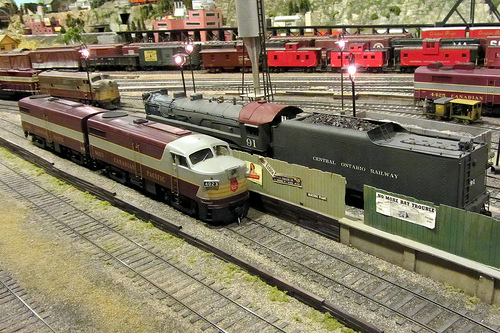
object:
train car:
[268, 111, 493, 215]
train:
[18, 93, 252, 226]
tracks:
[0, 160, 303, 333]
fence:
[361, 182, 499, 270]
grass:
[0, 186, 206, 333]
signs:
[375, 191, 436, 231]